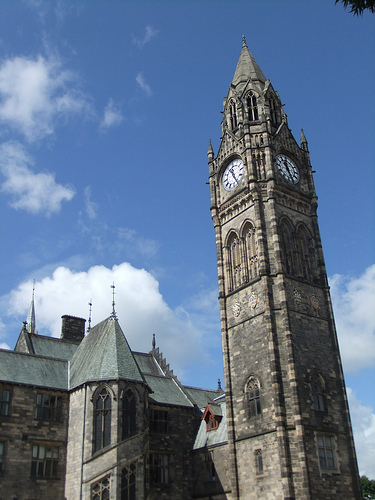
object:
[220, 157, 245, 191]
clock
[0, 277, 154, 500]
church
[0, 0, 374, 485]
sky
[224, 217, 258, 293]
window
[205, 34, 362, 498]
tower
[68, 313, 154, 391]
roof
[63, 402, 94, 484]
stone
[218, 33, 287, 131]
top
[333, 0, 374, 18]
tree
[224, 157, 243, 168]
twelve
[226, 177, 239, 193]
six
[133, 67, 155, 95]
cloud